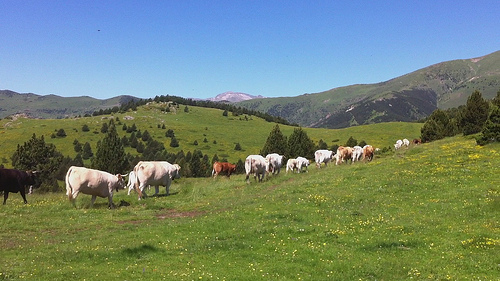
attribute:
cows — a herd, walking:
[5, 140, 375, 205]